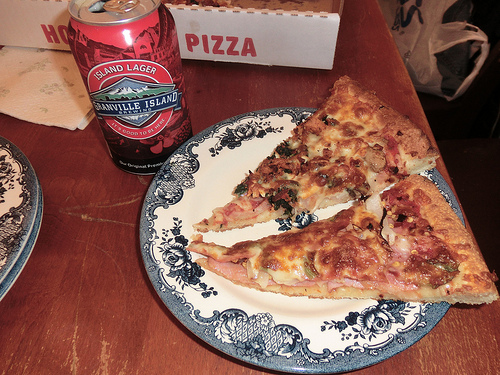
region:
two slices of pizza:
[196, 48, 497, 310]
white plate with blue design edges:
[139, 109, 469, 365]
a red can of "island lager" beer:
[64, 2, 195, 174]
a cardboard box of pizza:
[0, 3, 345, 70]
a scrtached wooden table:
[1, 2, 497, 374]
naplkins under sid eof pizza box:
[0, 45, 96, 130]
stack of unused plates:
[0, 134, 45, 310]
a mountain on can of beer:
[89, 78, 177, 94]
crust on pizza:
[329, 74, 498, 306]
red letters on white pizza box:
[41, 20, 263, 62]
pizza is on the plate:
[148, 106, 474, 373]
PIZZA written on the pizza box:
[185, 29, 261, 69]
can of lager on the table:
[64, 6, 210, 189]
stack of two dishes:
[5, 131, 57, 302]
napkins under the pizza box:
[1, 39, 125, 162]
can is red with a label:
[71, 2, 208, 176]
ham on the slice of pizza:
[294, 278, 411, 299]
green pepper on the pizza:
[302, 251, 316, 281]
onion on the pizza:
[361, 193, 426, 259]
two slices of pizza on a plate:
[173, 104, 472, 356]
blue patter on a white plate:
[178, 298, 360, 370]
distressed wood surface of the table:
[51, 223, 153, 366]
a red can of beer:
[51, 5, 200, 169]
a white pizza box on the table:
[171, 0, 329, 67]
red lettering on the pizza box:
[178, 21, 274, 68]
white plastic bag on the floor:
[385, 5, 475, 102]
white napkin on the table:
[0, 44, 87, 129]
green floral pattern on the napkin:
[16, 55, 86, 106]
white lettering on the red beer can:
[83, 58, 163, 85]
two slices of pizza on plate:
[212, 97, 468, 372]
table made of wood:
[60, 214, 114, 312]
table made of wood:
[37, 297, 162, 374]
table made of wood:
[432, 327, 460, 370]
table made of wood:
[207, 55, 294, 98]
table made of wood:
[50, 239, 172, 357]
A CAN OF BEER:
[64, 1, 199, 178]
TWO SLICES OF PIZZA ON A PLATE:
[137, 70, 496, 372]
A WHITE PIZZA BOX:
[2, 3, 344, 74]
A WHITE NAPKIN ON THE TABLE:
[0, 44, 107, 133]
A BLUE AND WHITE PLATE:
[136, 104, 466, 371]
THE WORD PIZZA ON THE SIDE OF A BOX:
[177, 5, 347, 75]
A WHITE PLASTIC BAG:
[376, 0, 493, 107]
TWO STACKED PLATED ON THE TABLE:
[1, 133, 49, 313]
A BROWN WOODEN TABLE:
[8, 5, 496, 372]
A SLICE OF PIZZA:
[186, 172, 498, 312]